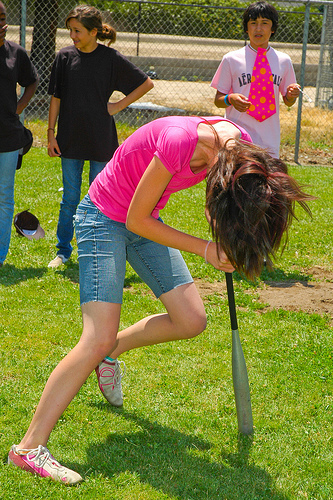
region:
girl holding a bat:
[35, 72, 317, 497]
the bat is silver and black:
[213, 250, 263, 459]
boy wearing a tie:
[228, 5, 303, 161]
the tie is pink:
[235, 30, 296, 126]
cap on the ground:
[2, 194, 44, 249]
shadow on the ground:
[81, 385, 227, 477]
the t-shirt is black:
[34, 41, 125, 133]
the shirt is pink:
[87, 112, 233, 268]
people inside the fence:
[0, 7, 328, 268]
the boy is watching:
[189, 4, 302, 197]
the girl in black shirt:
[42, 11, 125, 126]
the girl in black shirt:
[35, 8, 164, 169]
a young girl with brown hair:
[49, 4, 131, 56]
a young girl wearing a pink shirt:
[87, 127, 252, 227]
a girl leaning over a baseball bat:
[87, 140, 292, 300]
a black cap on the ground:
[4, 207, 54, 248]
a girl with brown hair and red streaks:
[197, 151, 309, 237]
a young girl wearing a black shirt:
[51, 19, 128, 127]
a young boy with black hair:
[231, 6, 287, 44]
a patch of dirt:
[240, 264, 326, 350]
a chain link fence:
[158, 20, 222, 69]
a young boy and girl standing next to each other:
[0, 0, 136, 142]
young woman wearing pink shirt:
[123, 119, 194, 197]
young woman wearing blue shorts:
[72, 212, 130, 312]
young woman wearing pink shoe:
[4, 439, 82, 483]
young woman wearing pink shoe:
[95, 361, 132, 403]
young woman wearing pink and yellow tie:
[252, 47, 284, 126]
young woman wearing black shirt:
[52, 48, 120, 147]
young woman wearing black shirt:
[0, 48, 38, 148]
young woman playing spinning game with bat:
[221, 282, 258, 445]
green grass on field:
[9, 275, 51, 364]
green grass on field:
[147, 358, 213, 475]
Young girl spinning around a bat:
[8, 113, 316, 482]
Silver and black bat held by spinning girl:
[220, 264, 253, 438]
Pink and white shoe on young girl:
[5, 440, 85, 484]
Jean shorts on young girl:
[69, 191, 193, 304]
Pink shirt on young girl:
[88, 112, 252, 225]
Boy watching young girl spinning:
[207, 5, 301, 152]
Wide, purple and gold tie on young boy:
[242, 43, 277, 121]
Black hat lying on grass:
[8, 208, 44, 240]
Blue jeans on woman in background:
[54, 151, 110, 258]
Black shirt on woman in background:
[47, 43, 148, 160]